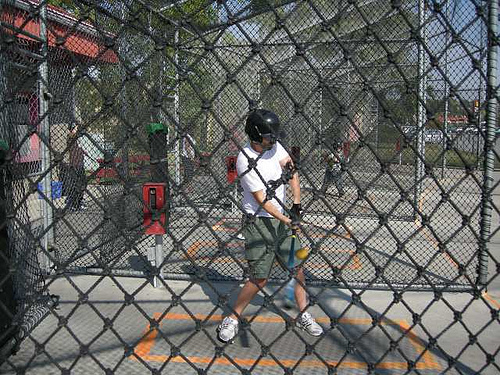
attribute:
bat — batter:
[284, 219, 303, 319]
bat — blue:
[274, 194, 312, 308]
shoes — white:
[217, 312, 324, 342]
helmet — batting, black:
[237, 105, 286, 149]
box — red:
[142, 181, 169, 231]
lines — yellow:
[123, 314, 423, 363]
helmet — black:
[242, 105, 283, 150]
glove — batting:
[285, 199, 305, 227]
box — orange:
[133, 303, 444, 373]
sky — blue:
[217, 5, 480, 123]